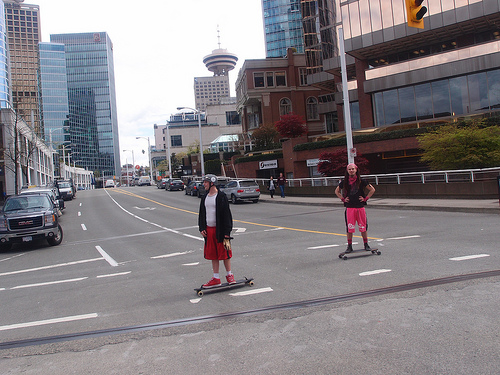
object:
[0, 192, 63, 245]
car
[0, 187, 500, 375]
ground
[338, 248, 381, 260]
skateboard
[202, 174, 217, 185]
helmet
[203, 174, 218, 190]
man's head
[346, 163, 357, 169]
bandana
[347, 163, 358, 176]
head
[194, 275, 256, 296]
skateboarder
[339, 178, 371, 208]
shirt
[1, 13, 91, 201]
short buildings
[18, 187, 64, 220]
cars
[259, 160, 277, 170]
sign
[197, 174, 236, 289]
guy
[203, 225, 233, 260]
shorts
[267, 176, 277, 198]
people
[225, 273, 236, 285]
shoe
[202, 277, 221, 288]
shoe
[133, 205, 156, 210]
arrow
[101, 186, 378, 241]
paved street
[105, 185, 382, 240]
yellow lines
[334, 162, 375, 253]
guy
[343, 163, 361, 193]
hair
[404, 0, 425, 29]
light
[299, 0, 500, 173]
building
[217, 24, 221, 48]
pole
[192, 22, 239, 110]
building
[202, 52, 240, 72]
ring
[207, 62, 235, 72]
ring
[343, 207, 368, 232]
shorts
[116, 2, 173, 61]
sky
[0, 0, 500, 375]
city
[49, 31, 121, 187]
building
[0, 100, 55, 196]
tree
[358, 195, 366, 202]
hands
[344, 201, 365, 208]
waist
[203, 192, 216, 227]
tank top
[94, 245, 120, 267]
line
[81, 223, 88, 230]
line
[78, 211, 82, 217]
line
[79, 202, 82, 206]
line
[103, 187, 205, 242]
line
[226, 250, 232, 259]
stripe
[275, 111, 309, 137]
leaves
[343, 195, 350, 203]
hands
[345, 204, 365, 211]
hips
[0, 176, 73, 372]
sidewalk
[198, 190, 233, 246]
jacket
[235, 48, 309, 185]
building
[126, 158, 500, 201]
street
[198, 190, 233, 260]
clothes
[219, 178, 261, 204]
car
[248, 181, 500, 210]
sidewalk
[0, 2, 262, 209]
distance